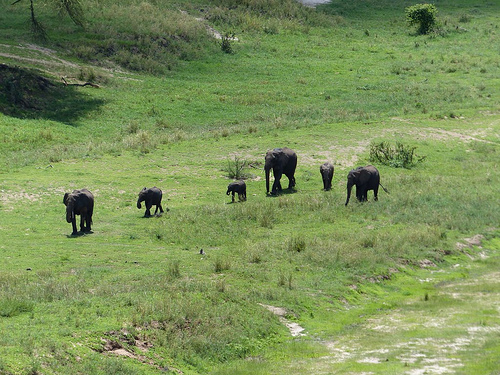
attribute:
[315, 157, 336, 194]
elephant — walking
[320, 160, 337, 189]
elephant — Small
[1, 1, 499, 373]
grass — green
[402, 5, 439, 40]
tree — green, small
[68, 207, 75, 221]
tusk — white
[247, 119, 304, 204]
elephant — dark, grey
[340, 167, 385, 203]
elephant — walking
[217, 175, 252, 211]
elephant — baby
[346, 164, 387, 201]
elephant — herd, six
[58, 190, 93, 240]
elephant — grey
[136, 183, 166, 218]
elephant — grey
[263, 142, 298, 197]
elephant — grey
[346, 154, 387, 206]
elephant — grey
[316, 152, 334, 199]
elephant — grey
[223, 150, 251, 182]
bush — leafless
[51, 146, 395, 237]
elephants — herd